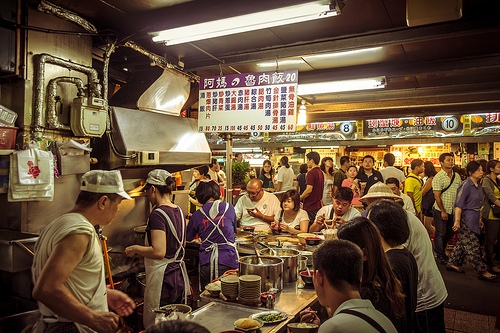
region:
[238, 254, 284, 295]
a large metal cooking pot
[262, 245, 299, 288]
a large metal cooking pot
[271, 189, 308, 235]
a woman eating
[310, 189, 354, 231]
a man eating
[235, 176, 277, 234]
a man eating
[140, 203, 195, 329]
a long white cooking apron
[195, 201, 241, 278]
the back of a long white cooking apron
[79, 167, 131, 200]
a white baseball hat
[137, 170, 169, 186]
a white baseball hat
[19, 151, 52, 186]
a white and red plastic bag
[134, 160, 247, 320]
two woman in purple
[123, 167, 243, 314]
two women wearing aprons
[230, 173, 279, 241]
man with a receding hairline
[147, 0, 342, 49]
florescent light fixture suspended from ceiling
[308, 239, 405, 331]
man with a strap on his shoulder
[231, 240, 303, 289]
two stainless pots with ladles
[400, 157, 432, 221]
person in bright yellow shirt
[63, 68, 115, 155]
gas meter mounted on the wall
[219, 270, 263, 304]
two stacks of soup bowls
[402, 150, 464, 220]
two people with straps on shoulders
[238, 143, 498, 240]
a crowd of people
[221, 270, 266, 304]
cups next to a pot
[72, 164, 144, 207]
a white baseball cap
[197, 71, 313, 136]
a sign hanging from the ceiling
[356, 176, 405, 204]
a full brimmed hat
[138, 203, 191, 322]
apron worn by a worker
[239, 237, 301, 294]
pots full of food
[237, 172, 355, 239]
people eating food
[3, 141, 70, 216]
bags for customers to take food to go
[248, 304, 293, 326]
a plate with food on it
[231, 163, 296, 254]
bald man eating food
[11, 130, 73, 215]
grocery bags hanging from oven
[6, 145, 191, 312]
man in white making food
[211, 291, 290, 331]
food on a counter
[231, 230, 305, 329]
different soups in pots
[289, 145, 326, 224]
man in maroon walking down the market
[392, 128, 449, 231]
man in yellow walking down the market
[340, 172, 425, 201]
man wearing a tan hat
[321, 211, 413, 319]
woman sitting and eating food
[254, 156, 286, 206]
woman walking down the market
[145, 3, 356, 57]
bright fluorescent tubed lighting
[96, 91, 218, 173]
industrial sized silver metal hood fan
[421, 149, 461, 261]
man in a plaid shirt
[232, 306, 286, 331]
plates of food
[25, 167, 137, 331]
man in a white shirt and trucker cap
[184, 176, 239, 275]
person wearing a purple shirt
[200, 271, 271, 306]
stacks of dishes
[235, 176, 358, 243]
people eating some food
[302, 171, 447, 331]
people waiting in line for food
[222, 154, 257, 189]
leafy green plant